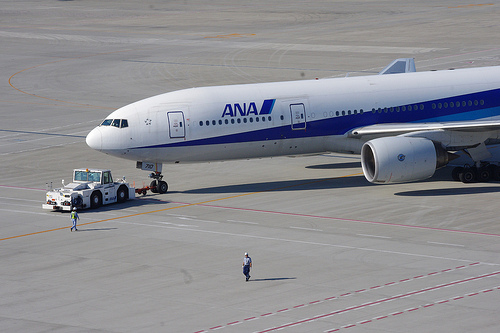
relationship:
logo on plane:
[208, 89, 285, 127] [81, 56, 498, 193]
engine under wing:
[359, 134, 454, 184] [348, 113, 498, 133]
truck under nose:
[41, 169, 135, 212] [85, 98, 136, 154]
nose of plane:
[85, 98, 136, 154] [81, 56, 498, 193]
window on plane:
[203, 119, 212, 129] [81, 56, 498, 193]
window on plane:
[207, 116, 218, 128] [81, 56, 498, 193]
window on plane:
[238, 115, 244, 125] [55, 28, 495, 172]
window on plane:
[256, 115, 262, 126] [60, 57, 499, 242]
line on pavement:
[197, 259, 482, 331] [1, 0, 497, 329]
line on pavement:
[197, 259, 500, 333] [1, 0, 497, 329]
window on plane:
[166, 108, 188, 140] [81, 56, 498, 193]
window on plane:
[408, 104, 412, 110] [81, 56, 498, 193]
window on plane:
[332, 109, 340, 116] [81, 56, 498, 193]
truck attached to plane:
[39, 163, 144, 216] [77, 56, 498, 218]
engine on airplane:
[359, 134, 454, 184] [84, 56, 500, 195]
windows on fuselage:
[195, 113, 303, 128] [86, 55, 498, 192]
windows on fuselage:
[335, 96, 485, 116] [86, 55, 498, 192]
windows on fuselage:
[98, 118, 129, 129] [86, 55, 498, 192]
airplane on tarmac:
[79, 51, 498, 211] [1, 0, 494, 330]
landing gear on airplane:
[147, 172, 175, 199] [84, 56, 500, 195]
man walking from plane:
[238, 251, 253, 281] [81, 56, 498, 193]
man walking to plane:
[49, 197, 79, 225] [109, 64, 464, 212]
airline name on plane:
[220, 101, 255, 116] [74, 62, 496, 186]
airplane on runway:
[84, 56, 500, 195] [1, 0, 498, 332]